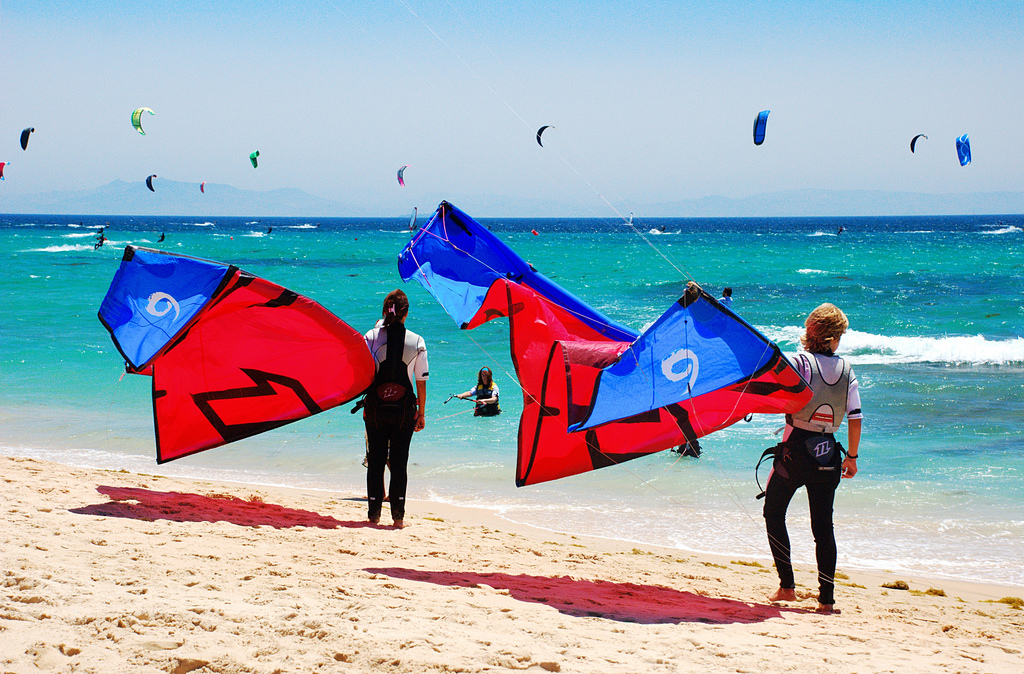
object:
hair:
[800, 302, 847, 353]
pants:
[762, 423, 841, 605]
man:
[762, 302, 864, 609]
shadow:
[361, 567, 821, 626]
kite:
[397, 198, 816, 491]